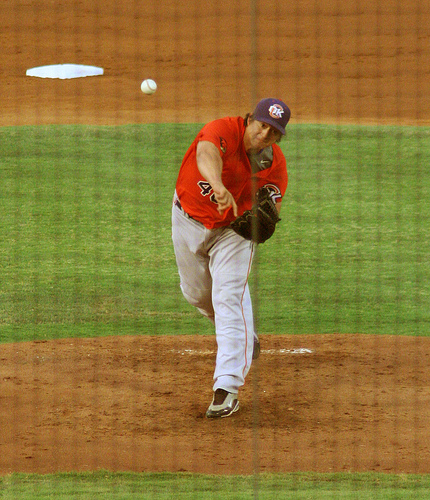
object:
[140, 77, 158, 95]
baseball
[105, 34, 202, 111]
air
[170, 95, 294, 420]
player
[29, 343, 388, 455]
in dirt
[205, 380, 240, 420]
left foot of player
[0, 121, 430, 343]
grass on field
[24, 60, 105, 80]
plate on field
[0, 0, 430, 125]
dirt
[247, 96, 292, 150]
pitcher's head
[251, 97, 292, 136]
blue cap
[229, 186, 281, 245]
mitt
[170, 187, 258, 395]
pants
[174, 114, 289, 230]
red shirt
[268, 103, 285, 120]
white design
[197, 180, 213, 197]
number 4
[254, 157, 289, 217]
left arm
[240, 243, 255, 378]
red stripe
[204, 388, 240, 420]
sneaker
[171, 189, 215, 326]
pitcher's right leg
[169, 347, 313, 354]
white line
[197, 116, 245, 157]
short sleeve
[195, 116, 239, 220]
pitcher's arm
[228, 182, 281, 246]
leather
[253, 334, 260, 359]
cleat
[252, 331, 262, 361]
pitcher's foot